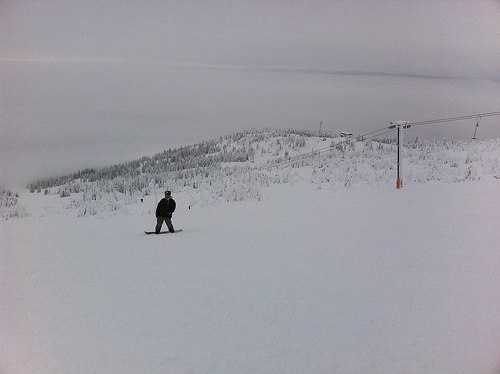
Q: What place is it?
A: It is a path.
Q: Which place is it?
A: It is a path.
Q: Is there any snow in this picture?
A: Yes, there is snow.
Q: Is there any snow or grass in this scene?
A: Yes, there is snow.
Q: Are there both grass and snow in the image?
A: No, there is snow but no grass.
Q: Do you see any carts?
A: No, there are no carts.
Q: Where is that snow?
A: The snow is on the ground.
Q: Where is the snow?
A: The snow is on the ground.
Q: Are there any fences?
A: No, there are no fences.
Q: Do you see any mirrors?
A: No, there are no mirrors.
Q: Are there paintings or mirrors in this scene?
A: No, there are no mirrors or paintings.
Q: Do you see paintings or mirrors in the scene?
A: No, there are no mirrors or paintings.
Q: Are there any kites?
A: No, there are no kites.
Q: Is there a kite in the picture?
A: No, there are no kites.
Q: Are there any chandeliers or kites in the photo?
A: No, there are no kites or chandeliers.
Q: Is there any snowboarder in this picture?
A: Yes, there is a snowboarder.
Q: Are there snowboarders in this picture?
A: Yes, there is a snowboarder.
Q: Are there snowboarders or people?
A: Yes, there is a snowboarder.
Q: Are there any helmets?
A: No, there are no helmets.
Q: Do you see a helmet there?
A: No, there are no helmets.